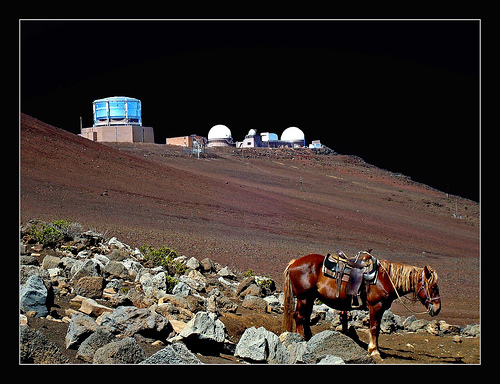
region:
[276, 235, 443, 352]
brown horse with blonde hair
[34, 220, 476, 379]
group of rocks surrounding brown horse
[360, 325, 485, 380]
shadow of horse on ground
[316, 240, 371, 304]
brown saddle on brown horse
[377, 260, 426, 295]
blonde mane ofhorse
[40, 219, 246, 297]
weeds growing through rocks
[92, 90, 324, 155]
buildings on the hilltop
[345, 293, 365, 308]
stirrups on saddle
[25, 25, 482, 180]
black sky behind hillside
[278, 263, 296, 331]
blonde hair of horse's tail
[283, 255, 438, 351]
A horse on the hill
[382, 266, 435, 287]
The mane of the horse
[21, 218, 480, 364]
Large rocks beside the horse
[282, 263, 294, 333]
The tail of the horse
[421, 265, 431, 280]
The right ear of the horse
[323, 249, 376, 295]
A saddle on teh horse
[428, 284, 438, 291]
The right eye of the horse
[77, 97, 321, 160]
Buildings on the hill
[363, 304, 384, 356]
The front legs of the horse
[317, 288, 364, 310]
The stomach of the horse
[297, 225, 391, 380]
This is a horse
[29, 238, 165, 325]
These are large rocks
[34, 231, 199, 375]
This is a pile of rocks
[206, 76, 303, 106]
The sky is black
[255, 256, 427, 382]
The horse is brown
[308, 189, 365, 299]
This is a saddle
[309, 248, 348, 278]
The saddle is leather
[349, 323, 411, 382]
This is a hoof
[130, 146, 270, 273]
This is red dirt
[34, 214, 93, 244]
This is a patch of grass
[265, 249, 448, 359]
Brown horse with a light brown mane.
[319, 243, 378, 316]
The horse is wearing saddle.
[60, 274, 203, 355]
Many rocks dot the hillside.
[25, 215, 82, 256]
Small green plants among the rocks.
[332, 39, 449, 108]
A very dark night sky.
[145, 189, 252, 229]
Dirt hill behind the horse.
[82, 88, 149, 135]
Bright blue water tower.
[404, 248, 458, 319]
The horse is looking at the ground.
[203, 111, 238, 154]
Looks like a telescope.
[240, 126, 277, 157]
Two buildings on the hill.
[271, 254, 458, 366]
HORSE STANDING BETWEEN ROCKS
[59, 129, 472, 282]
BROWN DIRT SLOPE IN BACKGROUND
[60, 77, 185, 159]
LARGE BLUE BOILER ON ROOF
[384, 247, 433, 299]
BLONDE MANE ON BROWN HORSE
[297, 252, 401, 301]
LEATHER SADDLE ON HORSE'S BACK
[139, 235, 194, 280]
SMALL GREEN BUSHES IN ROCKS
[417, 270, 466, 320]
HARNESS AROUND HORSE'S FACE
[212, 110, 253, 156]
WHITE GLOBE ON BUILDING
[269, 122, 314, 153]
WHITE GLOBE ON BUILDING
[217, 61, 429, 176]
DARK NIGHT SKY ABOVE